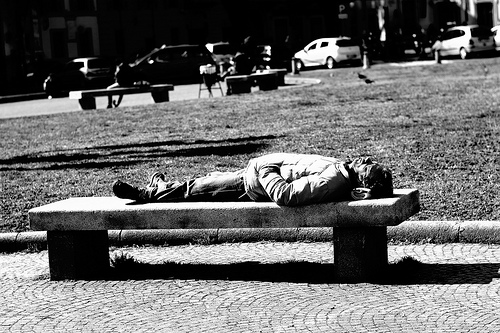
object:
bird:
[365, 79, 373, 84]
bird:
[358, 73, 366, 79]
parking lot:
[71, 29, 483, 83]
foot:
[113, 181, 141, 200]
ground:
[425, 124, 450, 161]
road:
[1, 68, 316, 116]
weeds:
[108, 251, 334, 280]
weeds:
[388, 252, 423, 272]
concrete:
[0, 240, 500, 331]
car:
[292, 36, 362, 70]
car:
[115, 45, 216, 88]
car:
[43, 57, 111, 93]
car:
[206, 41, 236, 70]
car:
[235, 44, 290, 73]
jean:
[139, 169, 246, 201]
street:
[3, 55, 498, 110]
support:
[333, 226, 388, 279]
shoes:
[113, 180, 141, 200]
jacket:
[243, 153, 350, 206]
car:
[432, 24, 495, 59]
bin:
[199, 64, 218, 99]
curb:
[0, 220, 498, 254]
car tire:
[295, 59, 304, 70]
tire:
[460, 48, 469, 59]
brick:
[32, 284, 441, 331]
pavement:
[18, 290, 491, 325]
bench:
[69, 84, 174, 110]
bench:
[263, 68, 287, 84]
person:
[106, 61, 132, 109]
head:
[348, 157, 382, 187]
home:
[374, 0, 500, 46]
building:
[0, 3, 140, 90]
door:
[77, 25, 92, 57]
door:
[49, 27, 70, 65]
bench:
[27, 188, 421, 281]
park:
[2, 62, 495, 330]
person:
[219, 52, 256, 96]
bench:
[225, 71, 278, 94]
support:
[47, 230, 110, 281]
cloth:
[351, 187, 373, 200]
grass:
[4, 58, 494, 218]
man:
[113, 153, 385, 205]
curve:
[1, 218, 498, 251]